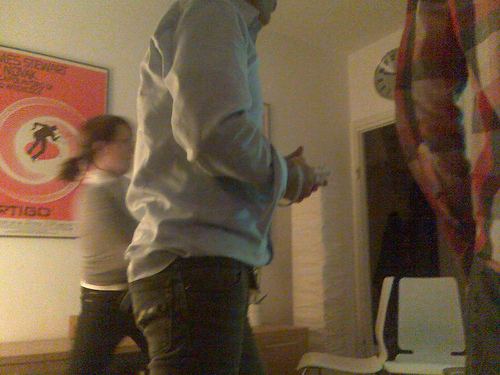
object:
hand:
[283, 154, 327, 205]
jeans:
[128, 256, 262, 375]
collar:
[82, 169, 120, 185]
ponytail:
[56, 155, 89, 182]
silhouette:
[27, 122, 61, 164]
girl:
[57, 114, 152, 375]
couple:
[53, 0, 330, 375]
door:
[360, 122, 437, 345]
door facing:
[350, 126, 372, 357]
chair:
[383, 276, 468, 375]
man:
[397, 0, 500, 373]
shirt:
[393, 1, 498, 274]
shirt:
[124, 0, 288, 282]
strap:
[278, 160, 302, 207]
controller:
[280, 165, 331, 207]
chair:
[295, 275, 397, 375]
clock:
[373, 48, 402, 101]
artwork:
[0, 43, 113, 238]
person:
[53, 104, 136, 368]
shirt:
[76, 166, 132, 291]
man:
[121, 0, 328, 375]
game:
[274, 164, 331, 208]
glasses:
[92, 134, 136, 143]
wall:
[0, 3, 296, 342]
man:
[26, 122, 61, 164]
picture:
[0, 43, 109, 237]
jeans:
[58, 286, 149, 375]